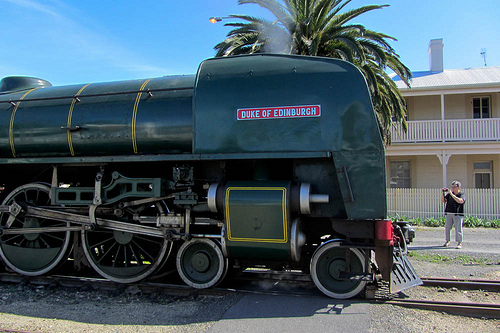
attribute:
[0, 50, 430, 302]
green train — large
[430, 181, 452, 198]
camera — black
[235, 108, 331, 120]
sign — red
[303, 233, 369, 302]
wheel — silver and black, metal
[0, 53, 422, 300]
train — large, locomotive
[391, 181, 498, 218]
railings — white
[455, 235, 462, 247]
shoe — white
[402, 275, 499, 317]
track — iron steel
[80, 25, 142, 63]
clouds — light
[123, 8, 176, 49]
sky — bright, blue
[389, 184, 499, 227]
railings — white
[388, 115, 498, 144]
railings — white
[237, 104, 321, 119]
sign — red and white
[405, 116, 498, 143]
balcony railing — white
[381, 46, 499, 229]
beige house — two-story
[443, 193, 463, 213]
shirt — black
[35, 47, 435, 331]
train. — dark green, locomotive